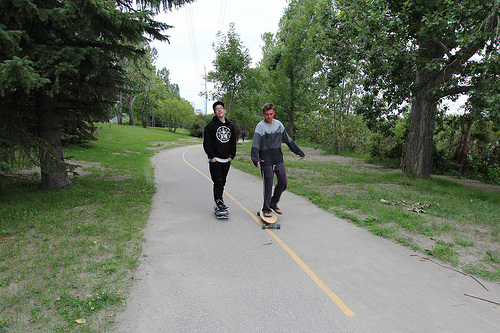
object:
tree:
[3, 0, 158, 202]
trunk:
[40, 129, 77, 199]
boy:
[258, 93, 311, 210]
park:
[1, 2, 498, 331]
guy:
[178, 65, 257, 222]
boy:
[202, 100, 237, 211]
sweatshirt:
[204, 112, 249, 164]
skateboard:
[254, 204, 285, 231]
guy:
[247, 100, 308, 218]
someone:
[238, 102, 307, 219]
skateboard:
[255, 200, 288, 231]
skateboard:
[212, 203, 227, 218]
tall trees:
[276, 4, 498, 114]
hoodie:
[198, 114, 270, 186]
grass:
[378, 179, 485, 233]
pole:
[203, 62, 208, 113]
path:
[113, 128, 498, 331]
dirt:
[39, 311, 52, 328]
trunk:
[411, 80, 443, 170]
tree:
[295, 5, 485, 185]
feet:
[258, 202, 273, 219]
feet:
[269, 197, 286, 215]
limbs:
[408, 249, 468, 280]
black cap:
[206, 97, 235, 114]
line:
[183, 145, 354, 331]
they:
[248, 99, 302, 219]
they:
[203, 96, 239, 213]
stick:
[463, 292, 498, 304]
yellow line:
[183, 151, 363, 332]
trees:
[1, 0, 175, 196]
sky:
[117, 1, 295, 113]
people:
[203, 93, 305, 223]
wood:
[379, 199, 446, 215]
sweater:
[250, 118, 299, 167]